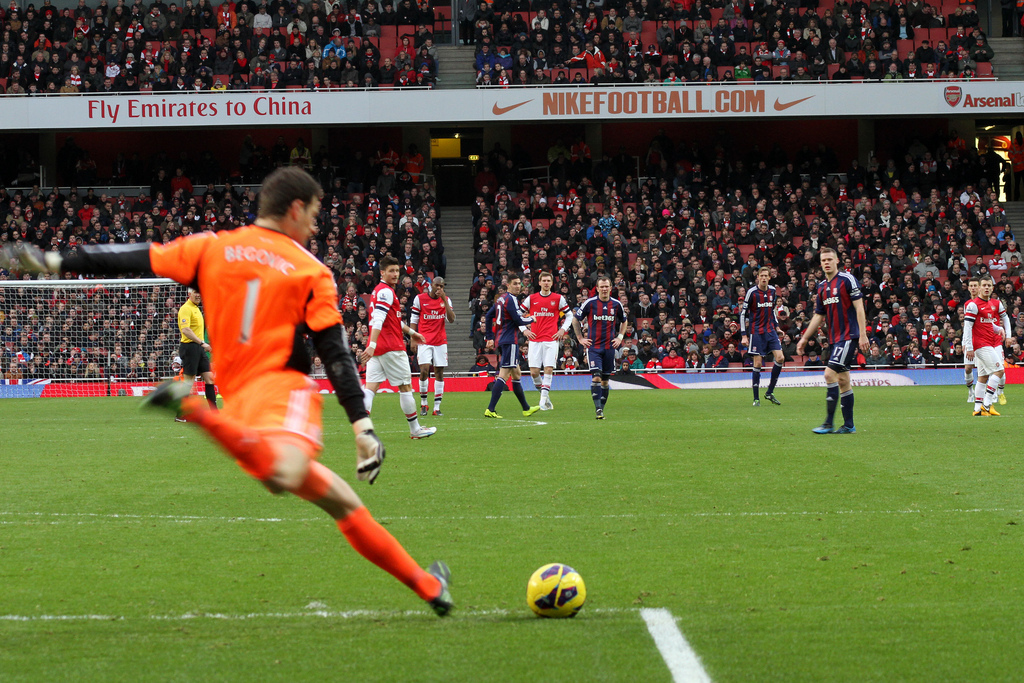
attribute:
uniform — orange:
[53, 221, 447, 608]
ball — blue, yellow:
[523, 556, 593, 627]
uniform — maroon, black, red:
[816, 269, 871, 437]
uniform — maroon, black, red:
[732, 280, 796, 401]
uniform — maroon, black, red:
[573, 294, 635, 415]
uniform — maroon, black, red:
[482, 292, 545, 415]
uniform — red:
[517, 294, 572, 406]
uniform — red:
[407, 295, 464, 411]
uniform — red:
[356, 284, 443, 444]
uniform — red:
[963, 296, 1019, 419]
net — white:
[2, 276, 210, 404]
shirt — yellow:
[163, 298, 216, 350]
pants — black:
[175, 339, 216, 381]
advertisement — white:
[0, 77, 1023, 126]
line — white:
[629, 591, 723, 680]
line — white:
[3, 500, 1022, 524]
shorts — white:
[361, 346, 419, 388]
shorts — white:
[414, 341, 456, 370]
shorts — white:
[522, 335, 564, 375]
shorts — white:
[968, 343, 1010, 379]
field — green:
[10, 385, 1023, 682]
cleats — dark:
[138, 367, 207, 415]